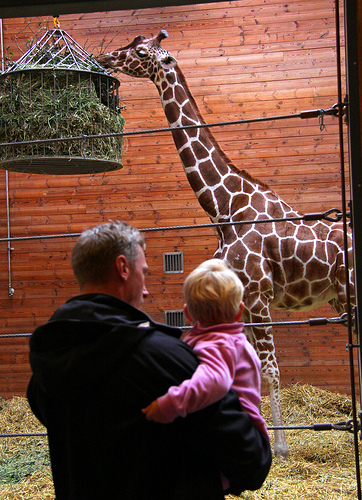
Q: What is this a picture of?
A: A giraffe.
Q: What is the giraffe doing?
A: Eating.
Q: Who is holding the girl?
A: The man.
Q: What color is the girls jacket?
A: Pink.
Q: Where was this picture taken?
A: At the zoo.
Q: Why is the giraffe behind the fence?
A: Safety.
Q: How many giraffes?
A: One.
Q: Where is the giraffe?
A: Behind a fence.